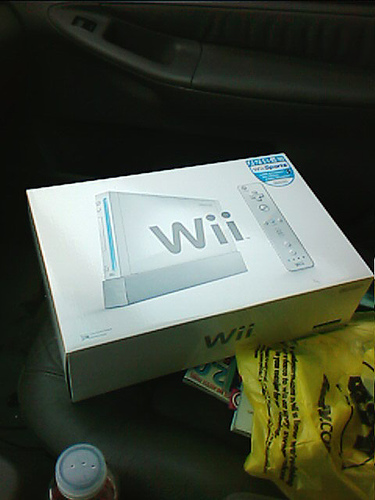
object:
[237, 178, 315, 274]
remote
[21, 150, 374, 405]
box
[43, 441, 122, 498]
drink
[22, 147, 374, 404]
wii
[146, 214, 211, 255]
letter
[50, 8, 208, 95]
door handle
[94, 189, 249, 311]
console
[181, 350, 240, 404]
magazine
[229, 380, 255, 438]
magazine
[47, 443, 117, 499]
bottle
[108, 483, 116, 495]
plastic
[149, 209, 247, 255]
writing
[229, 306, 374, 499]
bag